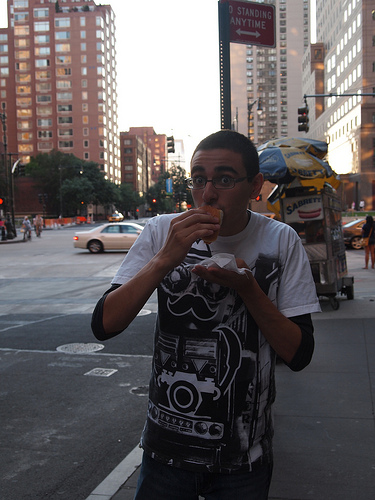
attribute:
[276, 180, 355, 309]
hotdog stand — cart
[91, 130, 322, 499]
man — young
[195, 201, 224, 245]
hot dog — partially eaten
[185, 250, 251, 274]
napkin — white, paper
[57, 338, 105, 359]
sewer cover — metal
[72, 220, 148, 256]
car — tan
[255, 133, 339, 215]
umbrellas — blue, yellow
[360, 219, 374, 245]
shirt — black, white, blue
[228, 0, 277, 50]
sign — red, white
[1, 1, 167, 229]
buildings — tall, red, brick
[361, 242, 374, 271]
pants — orange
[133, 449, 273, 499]
jeans — blue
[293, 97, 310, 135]
traffic light — black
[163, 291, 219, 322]
mustache — black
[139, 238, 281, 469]
graphics — black, white